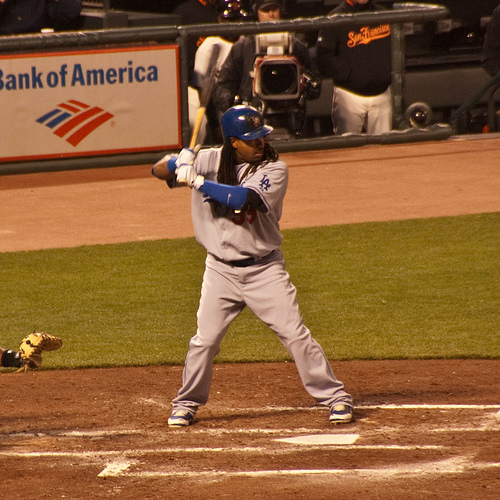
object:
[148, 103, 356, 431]
man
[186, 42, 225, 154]
bat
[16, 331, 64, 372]
glove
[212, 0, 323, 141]
cameraman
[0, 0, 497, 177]
dugout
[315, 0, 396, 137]
man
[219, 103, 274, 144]
helmet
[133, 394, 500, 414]
chalk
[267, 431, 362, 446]
base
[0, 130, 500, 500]
baseball field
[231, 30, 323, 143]
camera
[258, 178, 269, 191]
words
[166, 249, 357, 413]
baseball pants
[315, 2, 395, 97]
jacket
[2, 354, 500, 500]
baseball diamond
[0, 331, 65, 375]
catcher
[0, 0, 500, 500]
baseball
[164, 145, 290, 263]
shirt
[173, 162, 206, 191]
gloves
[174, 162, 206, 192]
hand